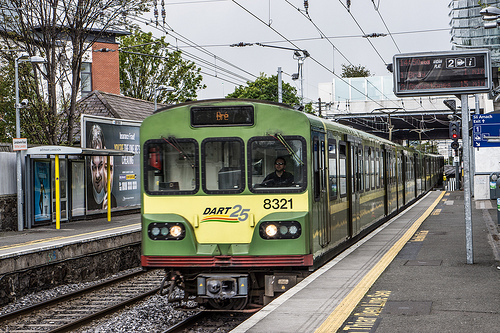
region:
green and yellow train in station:
[126, 85, 446, 303]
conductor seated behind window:
[240, 125, 316, 200]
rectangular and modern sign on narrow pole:
[380, 40, 495, 270]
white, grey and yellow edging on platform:
[247, 166, 448, 327]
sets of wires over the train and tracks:
[87, 2, 432, 112]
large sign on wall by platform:
[70, 102, 137, 232]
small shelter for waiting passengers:
[12, 130, 127, 235]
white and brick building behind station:
[12, 12, 137, 162]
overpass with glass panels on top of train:
[282, 56, 468, 117]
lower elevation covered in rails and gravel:
[6, 182, 304, 328]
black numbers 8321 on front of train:
[259, 196, 303, 211]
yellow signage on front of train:
[143, 195, 305, 226]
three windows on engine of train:
[143, 133, 307, 195]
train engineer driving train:
[248, 139, 303, 186]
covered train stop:
[17, 139, 127, 231]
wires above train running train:
[231, 31, 372, 105]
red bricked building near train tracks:
[21, 17, 122, 92]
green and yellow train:
[139, 108, 443, 313]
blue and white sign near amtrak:
[470, 111, 499, 149]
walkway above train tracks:
[315, 78, 491, 115]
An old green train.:
[385, 72, 499, 189]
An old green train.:
[164, 91, 258, 191]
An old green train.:
[178, 102, 323, 274]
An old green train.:
[151, 24, 365, 266]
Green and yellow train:
[119, 91, 446, 318]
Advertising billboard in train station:
[71, 102, 146, 222]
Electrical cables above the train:
[128, 0, 454, 162]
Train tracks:
[9, 259, 163, 330]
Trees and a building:
[3, 5, 196, 142]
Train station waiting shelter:
[16, 133, 128, 230]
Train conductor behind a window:
[246, 126, 308, 202]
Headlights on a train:
[131, 189, 319, 265]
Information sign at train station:
[388, 43, 495, 265]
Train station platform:
[346, 167, 489, 322]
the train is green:
[106, 90, 475, 290]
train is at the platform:
[103, 72, 373, 309]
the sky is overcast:
[153, 22, 423, 87]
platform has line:
[356, 223, 459, 326]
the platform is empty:
[392, 131, 488, 307]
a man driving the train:
[175, 130, 315, 211]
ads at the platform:
[42, 89, 194, 246]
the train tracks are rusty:
[58, 276, 138, 321]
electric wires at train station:
[79, 15, 434, 146]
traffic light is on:
[437, 106, 472, 212]